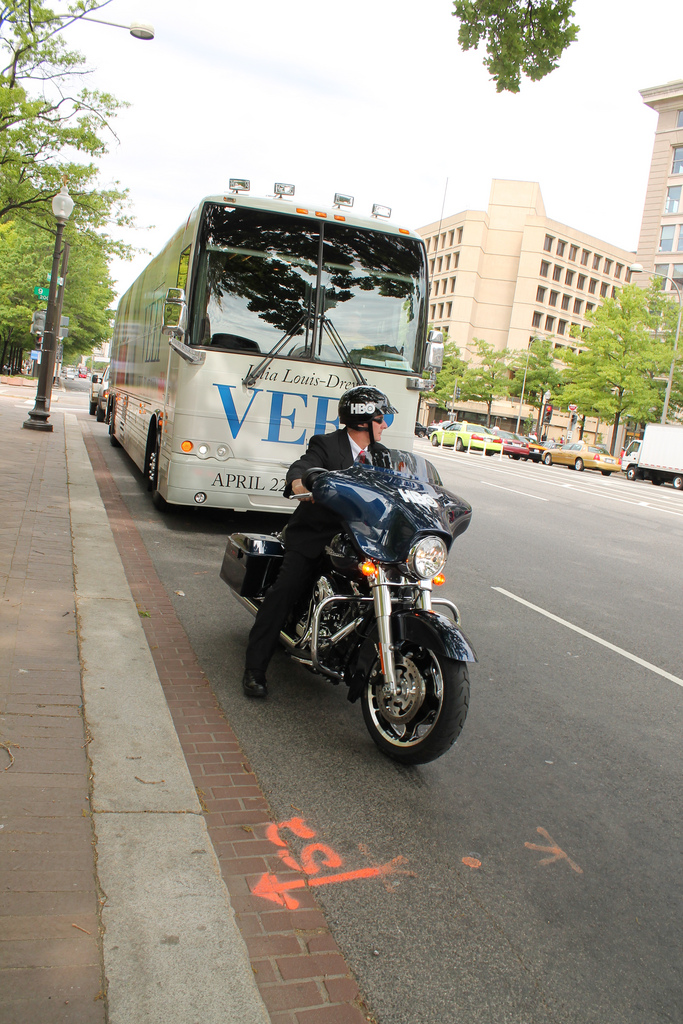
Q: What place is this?
A: It is a street.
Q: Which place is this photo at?
A: It is at the street.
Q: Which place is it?
A: It is a street.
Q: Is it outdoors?
A: Yes, it is outdoors.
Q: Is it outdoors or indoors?
A: It is outdoors.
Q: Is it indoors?
A: No, it is outdoors.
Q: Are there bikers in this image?
A: Yes, there is a biker.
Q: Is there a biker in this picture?
A: Yes, there is a biker.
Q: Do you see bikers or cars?
A: Yes, there is a biker.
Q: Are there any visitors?
A: No, there are no visitors.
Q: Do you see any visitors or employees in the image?
A: No, there are no visitors or employees.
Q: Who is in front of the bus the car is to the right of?
A: The motorcyclist is in front of the bus.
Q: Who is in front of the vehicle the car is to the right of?
A: The motorcyclist is in front of the bus.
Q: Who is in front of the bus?
A: The motorcyclist is in front of the bus.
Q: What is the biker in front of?
A: The biker is in front of the bus.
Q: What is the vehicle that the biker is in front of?
A: The vehicle is a bus.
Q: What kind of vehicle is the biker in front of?
A: The biker is in front of the bus.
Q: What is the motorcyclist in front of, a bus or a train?
A: The motorcyclist is in front of a bus.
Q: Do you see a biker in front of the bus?
A: Yes, there is a biker in front of the bus.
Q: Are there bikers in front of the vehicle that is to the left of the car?
A: Yes, there is a biker in front of the bus.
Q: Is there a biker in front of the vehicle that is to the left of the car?
A: Yes, there is a biker in front of the bus.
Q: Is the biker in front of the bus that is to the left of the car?
A: Yes, the biker is in front of the bus.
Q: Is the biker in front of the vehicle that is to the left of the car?
A: Yes, the biker is in front of the bus.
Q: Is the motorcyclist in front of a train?
A: No, the motorcyclist is in front of the bus.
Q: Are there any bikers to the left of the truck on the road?
A: Yes, there is a biker to the left of the truck.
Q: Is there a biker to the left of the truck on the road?
A: Yes, there is a biker to the left of the truck.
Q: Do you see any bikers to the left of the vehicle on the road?
A: Yes, there is a biker to the left of the truck.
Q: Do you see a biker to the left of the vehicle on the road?
A: Yes, there is a biker to the left of the truck.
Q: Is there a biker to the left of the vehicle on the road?
A: Yes, there is a biker to the left of the truck.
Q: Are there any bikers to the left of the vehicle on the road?
A: Yes, there is a biker to the left of the truck.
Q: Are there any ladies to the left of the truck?
A: No, there is a biker to the left of the truck.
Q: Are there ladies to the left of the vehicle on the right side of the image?
A: No, there is a biker to the left of the truck.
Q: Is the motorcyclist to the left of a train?
A: No, the motorcyclist is to the left of the truck.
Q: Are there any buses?
A: Yes, there is a bus.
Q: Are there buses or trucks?
A: Yes, there is a bus.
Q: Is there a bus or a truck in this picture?
A: Yes, there is a bus.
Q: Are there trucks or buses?
A: Yes, there is a bus.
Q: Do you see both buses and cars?
A: Yes, there are both a bus and a car.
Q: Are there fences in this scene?
A: No, there are no fences.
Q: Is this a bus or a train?
A: This is a bus.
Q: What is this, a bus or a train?
A: This is a bus.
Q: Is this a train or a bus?
A: This is a bus.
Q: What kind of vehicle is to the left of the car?
A: The vehicle is a bus.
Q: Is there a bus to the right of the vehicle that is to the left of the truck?
A: No, the bus is to the left of the car.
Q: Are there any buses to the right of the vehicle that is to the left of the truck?
A: No, the bus is to the left of the car.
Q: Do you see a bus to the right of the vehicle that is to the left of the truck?
A: No, the bus is to the left of the car.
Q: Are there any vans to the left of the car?
A: No, there is a bus to the left of the car.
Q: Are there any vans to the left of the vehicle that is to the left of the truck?
A: No, there is a bus to the left of the car.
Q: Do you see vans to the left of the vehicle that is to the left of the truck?
A: No, there is a bus to the left of the car.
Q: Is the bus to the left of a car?
A: Yes, the bus is to the left of a car.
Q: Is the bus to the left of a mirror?
A: No, the bus is to the left of a car.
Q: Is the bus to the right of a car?
A: No, the bus is to the left of a car.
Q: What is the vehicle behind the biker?
A: The vehicle is a bus.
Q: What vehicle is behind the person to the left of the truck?
A: The vehicle is a bus.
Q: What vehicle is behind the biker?
A: The vehicle is a bus.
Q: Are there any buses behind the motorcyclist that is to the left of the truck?
A: Yes, there is a bus behind the motorcyclist.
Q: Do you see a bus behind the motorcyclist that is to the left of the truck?
A: Yes, there is a bus behind the motorcyclist.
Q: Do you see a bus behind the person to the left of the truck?
A: Yes, there is a bus behind the motorcyclist.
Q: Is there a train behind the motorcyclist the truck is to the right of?
A: No, there is a bus behind the motorcyclist.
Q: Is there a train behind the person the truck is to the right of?
A: No, there is a bus behind the motorcyclist.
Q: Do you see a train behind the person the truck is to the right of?
A: No, there is a bus behind the motorcyclist.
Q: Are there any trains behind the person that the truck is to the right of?
A: No, there is a bus behind the motorcyclist.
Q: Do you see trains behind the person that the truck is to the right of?
A: No, there is a bus behind the motorcyclist.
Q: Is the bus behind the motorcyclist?
A: Yes, the bus is behind the motorcyclist.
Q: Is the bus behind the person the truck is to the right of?
A: Yes, the bus is behind the motorcyclist.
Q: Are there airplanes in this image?
A: No, there are no airplanes.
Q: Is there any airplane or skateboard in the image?
A: No, there are no airplanes or skateboards.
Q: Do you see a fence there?
A: No, there are no fences.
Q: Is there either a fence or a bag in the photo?
A: No, there are no fences or bags.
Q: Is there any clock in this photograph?
A: No, there are no clocks.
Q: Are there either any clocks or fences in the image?
A: No, there are no clocks or fences.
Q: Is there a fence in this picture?
A: No, there are no fences.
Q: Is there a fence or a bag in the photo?
A: No, there are no fences or bags.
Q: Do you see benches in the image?
A: No, there are no benches.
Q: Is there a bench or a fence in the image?
A: No, there are no benches or fences.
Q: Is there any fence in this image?
A: No, there are no fences.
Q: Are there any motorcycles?
A: Yes, there is a motorcycle.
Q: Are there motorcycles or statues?
A: Yes, there is a motorcycle.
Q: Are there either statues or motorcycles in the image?
A: Yes, there is a motorcycle.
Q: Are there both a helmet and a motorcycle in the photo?
A: Yes, there are both a motorcycle and a helmet.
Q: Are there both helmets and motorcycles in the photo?
A: Yes, there are both a motorcycle and a helmet.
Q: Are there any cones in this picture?
A: No, there are no cones.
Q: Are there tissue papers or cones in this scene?
A: No, there are no cones or tissue papers.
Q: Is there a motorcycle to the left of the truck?
A: Yes, there is a motorcycle to the left of the truck.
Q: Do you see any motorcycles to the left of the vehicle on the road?
A: Yes, there is a motorcycle to the left of the truck.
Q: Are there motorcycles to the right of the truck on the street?
A: No, the motorcycle is to the left of the truck.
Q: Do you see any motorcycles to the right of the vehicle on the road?
A: No, the motorcycle is to the left of the truck.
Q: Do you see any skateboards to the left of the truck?
A: No, there is a motorcycle to the left of the truck.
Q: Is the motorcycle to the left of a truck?
A: Yes, the motorcycle is to the left of a truck.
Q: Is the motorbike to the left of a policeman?
A: No, the motorbike is to the left of a truck.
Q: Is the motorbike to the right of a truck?
A: No, the motorbike is to the left of a truck.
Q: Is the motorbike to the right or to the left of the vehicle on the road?
A: The motorbike is to the left of the truck.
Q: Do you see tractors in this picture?
A: No, there are no tractors.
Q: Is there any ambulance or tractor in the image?
A: No, there are no tractors or ambulances.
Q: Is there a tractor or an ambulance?
A: No, there are no tractors or ambulances.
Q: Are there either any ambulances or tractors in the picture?
A: No, there are no tractors or ambulances.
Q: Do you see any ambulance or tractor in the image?
A: No, there are no tractors or ambulances.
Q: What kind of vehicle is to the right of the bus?
A: The vehicle is a car.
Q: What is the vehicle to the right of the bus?
A: The vehicle is a car.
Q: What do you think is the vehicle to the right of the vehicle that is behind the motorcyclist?
A: The vehicle is a car.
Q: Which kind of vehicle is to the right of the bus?
A: The vehicle is a car.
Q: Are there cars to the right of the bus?
A: Yes, there is a car to the right of the bus.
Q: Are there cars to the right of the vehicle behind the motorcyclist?
A: Yes, there is a car to the right of the bus.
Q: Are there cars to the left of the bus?
A: No, the car is to the right of the bus.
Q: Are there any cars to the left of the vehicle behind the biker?
A: No, the car is to the right of the bus.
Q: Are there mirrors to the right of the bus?
A: No, there is a car to the right of the bus.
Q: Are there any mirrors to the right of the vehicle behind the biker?
A: No, there is a car to the right of the bus.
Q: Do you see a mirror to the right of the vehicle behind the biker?
A: No, there is a car to the right of the bus.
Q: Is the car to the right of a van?
A: No, the car is to the right of the bus.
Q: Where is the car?
A: The car is on the street.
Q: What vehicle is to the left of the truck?
A: The vehicle is a car.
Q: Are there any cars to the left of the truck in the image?
A: Yes, there is a car to the left of the truck.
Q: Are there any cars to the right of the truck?
A: No, the car is to the left of the truck.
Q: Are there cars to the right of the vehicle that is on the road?
A: No, the car is to the left of the truck.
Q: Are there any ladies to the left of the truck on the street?
A: No, there is a car to the left of the truck.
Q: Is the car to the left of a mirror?
A: No, the car is to the left of a truck.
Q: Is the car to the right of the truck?
A: No, the car is to the left of the truck.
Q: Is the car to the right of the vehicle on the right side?
A: No, the car is to the left of the truck.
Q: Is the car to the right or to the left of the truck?
A: The car is to the left of the truck.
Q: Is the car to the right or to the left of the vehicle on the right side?
A: The car is to the left of the truck.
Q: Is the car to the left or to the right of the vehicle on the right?
A: The car is to the left of the truck.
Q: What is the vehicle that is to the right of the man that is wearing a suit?
A: The vehicle is a car.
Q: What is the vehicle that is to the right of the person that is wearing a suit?
A: The vehicle is a car.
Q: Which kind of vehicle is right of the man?
A: The vehicle is a car.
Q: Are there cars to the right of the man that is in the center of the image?
A: Yes, there is a car to the right of the man.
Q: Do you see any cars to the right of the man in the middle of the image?
A: Yes, there is a car to the right of the man.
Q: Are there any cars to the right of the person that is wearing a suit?
A: Yes, there is a car to the right of the man.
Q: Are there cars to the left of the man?
A: No, the car is to the right of the man.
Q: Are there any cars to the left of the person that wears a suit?
A: No, the car is to the right of the man.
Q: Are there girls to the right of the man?
A: No, there is a car to the right of the man.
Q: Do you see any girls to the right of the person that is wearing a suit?
A: No, there is a car to the right of the man.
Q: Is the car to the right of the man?
A: Yes, the car is to the right of the man.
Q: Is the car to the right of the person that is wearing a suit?
A: Yes, the car is to the right of the man.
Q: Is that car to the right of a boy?
A: No, the car is to the right of the man.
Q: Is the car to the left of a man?
A: No, the car is to the right of a man.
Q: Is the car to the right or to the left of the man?
A: The car is to the right of the man.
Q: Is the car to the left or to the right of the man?
A: The car is to the right of the man.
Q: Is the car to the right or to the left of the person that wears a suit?
A: The car is to the right of the man.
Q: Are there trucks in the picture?
A: Yes, there is a truck.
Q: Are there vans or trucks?
A: Yes, there is a truck.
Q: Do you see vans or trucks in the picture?
A: Yes, there is a truck.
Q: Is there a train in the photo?
A: No, there are no trains.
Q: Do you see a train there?
A: No, there are no trains.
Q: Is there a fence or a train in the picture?
A: No, there are no trains or fences.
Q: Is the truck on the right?
A: Yes, the truck is on the right of the image.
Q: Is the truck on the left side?
A: No, the truck is on the right of the image.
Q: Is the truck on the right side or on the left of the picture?
A: The truck is on the right of the image.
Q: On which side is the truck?
A: The truck is on the right of the image.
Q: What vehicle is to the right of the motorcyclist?
A: The vehicle is a truck.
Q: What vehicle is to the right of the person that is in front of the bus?
A: The vehicle is a truck.